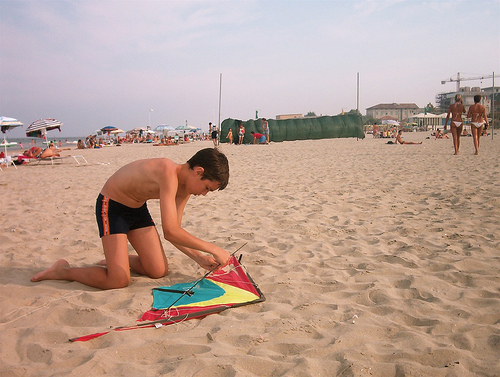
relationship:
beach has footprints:
[0, 145, 500, 377] [289, 184, 334, 213]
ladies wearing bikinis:
[432, 88, 492, 159] [451, 118, 483, 128]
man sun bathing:
[395, 128, 424, 151] [386, 129, 410, 152]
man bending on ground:
[249, 126, 269, 148] [383, 173, 413, 210]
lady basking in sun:
[22, 145, 60, 160] [81, 72, 130, 95]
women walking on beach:
[446, 94, 480, 159] [266, 168, 352, 193]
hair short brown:
[475, 91, 483, 102] [472, 94, 484, 99]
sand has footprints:
[263, 176, 312, 200] [289, 184, 334, 213]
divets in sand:
[274, 199, 306, 213] [263, 176, 312, 200]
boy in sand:
[95, 233, 170, 288] [263, 176, 312, 200]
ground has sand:
[282, 154, 328, 182] [263, 176, 312, 200]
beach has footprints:
[266, 168, 352, 193] [289, 184, 334, 213]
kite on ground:
[205, 275, 241, 305] [282, 154, 328, 182]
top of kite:
[255, 287, 267, 302] [205, 275, 241, 305]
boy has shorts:
[30, 147, 229, 290] [93, 202, 154, 228]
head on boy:
[187, 148, 232, 188] [30, 147, 229, 290]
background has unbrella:
[157, 35, 313, 128] [30, 117, 60, 136]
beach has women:
[266, 168, 352, 193] [446, 94, 480, 159]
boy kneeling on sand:
[30, 147, 229, 290] [263, 176, 312, 200]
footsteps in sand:
[377, 181, 448, 198] [263, 176, 312, 200]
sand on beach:
[263, 176, 312, 200] [266, 168, 352, 193]